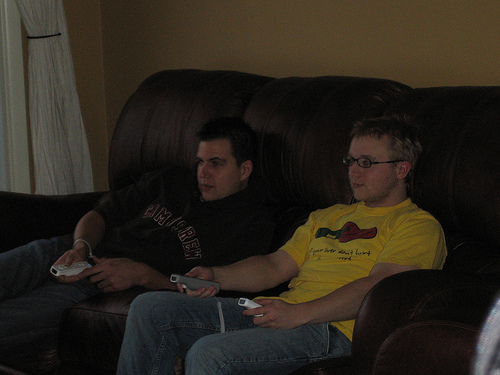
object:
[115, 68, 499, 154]
dark leather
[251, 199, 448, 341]
yellow shirt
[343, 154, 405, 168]
glasses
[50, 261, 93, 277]
wii control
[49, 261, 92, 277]
hand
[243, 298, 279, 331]
fingers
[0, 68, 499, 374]
couch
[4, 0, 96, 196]
curtain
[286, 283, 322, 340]
wrist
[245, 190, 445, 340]
yellow shirt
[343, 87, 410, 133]
ground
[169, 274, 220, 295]
game controller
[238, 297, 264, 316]
game controller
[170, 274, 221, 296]
wii remote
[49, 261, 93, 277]
wii remote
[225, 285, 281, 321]
wii remote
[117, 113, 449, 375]
guy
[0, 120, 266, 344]
guy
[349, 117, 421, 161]
hair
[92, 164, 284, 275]
black shirt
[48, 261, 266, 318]
remotes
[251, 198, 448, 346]
shirt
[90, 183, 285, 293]
shirt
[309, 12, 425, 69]
wall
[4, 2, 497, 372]
room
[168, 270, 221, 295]
wii remote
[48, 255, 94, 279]
wii remote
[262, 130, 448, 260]
no redshirt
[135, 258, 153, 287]
wrist